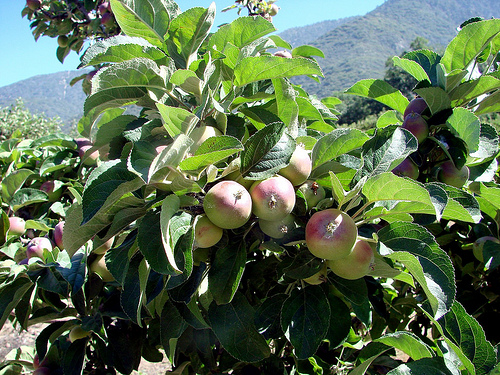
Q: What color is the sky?
A: Light Blue.